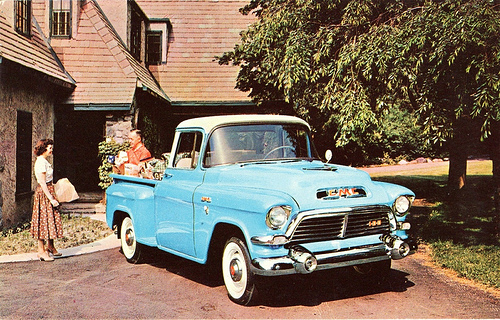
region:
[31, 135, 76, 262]
a woman wearing a dress and white blouse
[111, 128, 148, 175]
a man standing by a truck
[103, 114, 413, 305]
a blue GMC pickup truck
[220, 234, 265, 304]
a truck's front right wheel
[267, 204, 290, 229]
a truck's right headlight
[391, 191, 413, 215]
a truck's left headlight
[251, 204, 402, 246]
the grill of a blue truck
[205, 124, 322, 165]
a truck's windshield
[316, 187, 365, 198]
a blue trucks manufacturer logo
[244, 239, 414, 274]
front bumper of a blue truck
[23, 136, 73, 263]
a person standing up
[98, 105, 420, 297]
a parked car around people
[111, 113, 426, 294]
the car is light blue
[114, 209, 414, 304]
wheels on the car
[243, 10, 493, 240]
a tree beside the car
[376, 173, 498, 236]
the shadow of the tree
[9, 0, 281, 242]
a house beside the standing people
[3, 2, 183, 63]
the windows of the house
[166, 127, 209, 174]
the window of the car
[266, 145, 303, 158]
the steering wheel of the car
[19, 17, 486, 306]
an old picture of a family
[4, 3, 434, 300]
this picture was taken during the middle 1900s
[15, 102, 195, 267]
this man is bringing home groceries to his wife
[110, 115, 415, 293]
this is a nice blue pickup truck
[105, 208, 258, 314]
this pickup truck has white walls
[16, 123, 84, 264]
this lady looks happy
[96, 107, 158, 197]
this man is holding groceries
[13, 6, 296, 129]
this is a big house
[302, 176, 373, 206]
this is the name of the truck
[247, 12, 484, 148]
a big tree in the yard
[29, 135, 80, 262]
A woman standing in the driveway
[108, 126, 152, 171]
A man behind the truck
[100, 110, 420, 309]
An old light blue truck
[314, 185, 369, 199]
The logo on the front of the truck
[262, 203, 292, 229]
The right front headlight on the truck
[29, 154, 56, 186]
A light colored blouse on the woman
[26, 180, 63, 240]
A patterned dress on the woman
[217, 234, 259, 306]
The right front wheel on the truck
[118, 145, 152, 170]
An orange shirt on the man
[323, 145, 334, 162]
A driver's side rear view mirror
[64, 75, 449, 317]
the truck is blue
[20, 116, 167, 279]
two people are talking